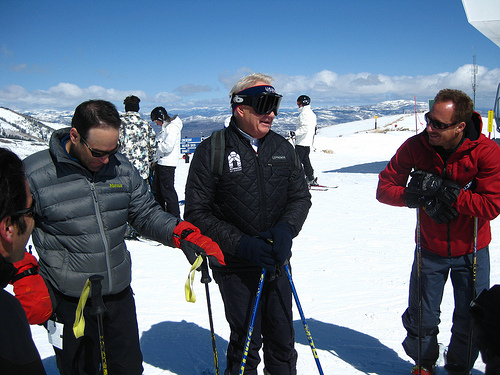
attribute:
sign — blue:
[174, 132, 201, 155]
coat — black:
[202, 141, 349, 279]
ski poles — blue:
[235, 237, 326, 349]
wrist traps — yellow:
[163, 253, 218, 302]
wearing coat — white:
[197, 140, 300, 242]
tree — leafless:
[450, 41, 493, 115]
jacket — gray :
[186, 137, 305, 239]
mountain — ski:
[251, 61, 431, 167]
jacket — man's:
[54, 206, 123, 269]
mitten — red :
[169, 220, 232, 274]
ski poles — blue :
[236, 267, 267, 374]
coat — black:
[183, 121, 320, 269]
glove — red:
[172, 212, 222, 267]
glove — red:
[12, 250, 52, 323]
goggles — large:
[234, 87, 281, 114]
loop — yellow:
[69, 277, 94, 346]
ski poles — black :
[409, 200, 483, 362]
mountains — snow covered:
[3, 91, 453, 157]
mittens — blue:
[236, 223, 302, 277]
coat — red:
[373, 132, 498, 254]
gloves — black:
[395, 152, 485, 224]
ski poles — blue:
[235, 239, 327, 373]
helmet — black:
[289, 86, 318, 106]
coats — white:
[145, 115, 192, 173]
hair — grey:
[226, 67, 275, 92]